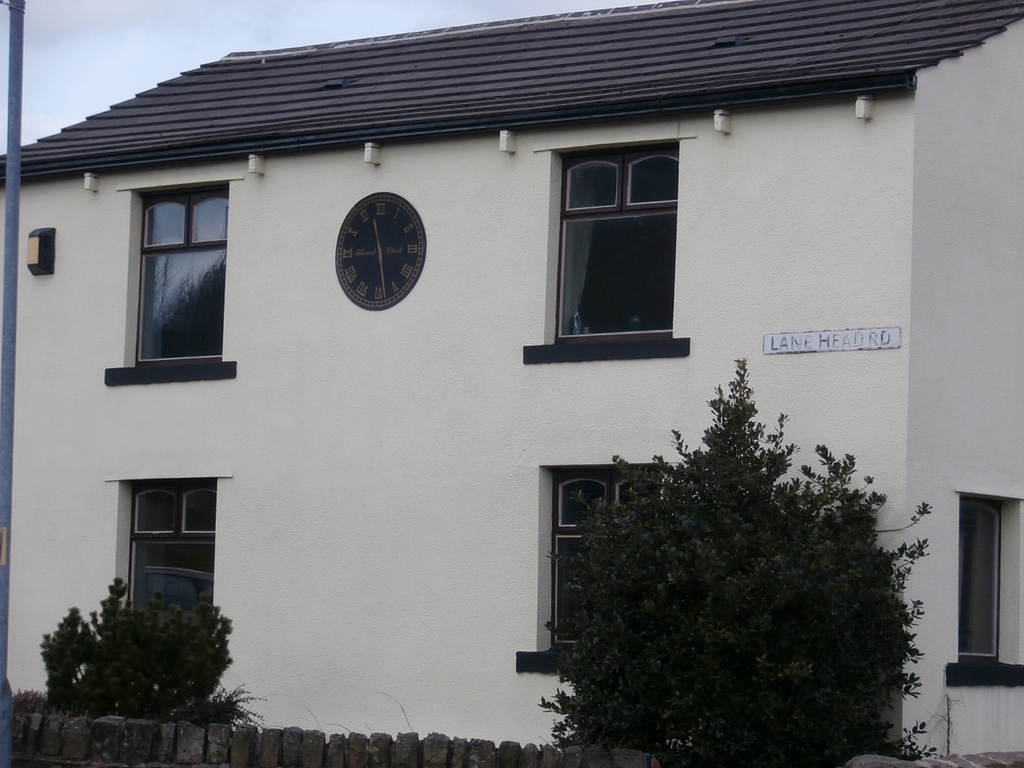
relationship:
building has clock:
[2, 1, 1024, 754] [325, 185, 440, 310]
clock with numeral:
[334, 190, 427, 311] [405, 256, 419, 283]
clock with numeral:
[334, 190, 427, 311] [400, 237, 420, 254]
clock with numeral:
[334, 190, 427, 311] [394, 218, 417, 235]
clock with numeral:
[334, 190, 427, 311] [367, 188, 393, 217]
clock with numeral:
[334, 190, 427, 311] [369, 285, 393, 304]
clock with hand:
[334, 190, 427, 311] [372, 213, 388, 248]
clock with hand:
[334, 190, 427, 311] [373, 242, 394, 306]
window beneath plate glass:
[106, 470, 215, 557] [187, 199, 230, 244]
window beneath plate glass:
[106, 470, 215, 557] [141, 199, 187, 244]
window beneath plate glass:
[106, 470, 215, 557] [177, 481, 215, 535]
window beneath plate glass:
[106, 470, 215, 557] [136, 481, 176, 535]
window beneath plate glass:
[544, 529, 586, 651] [612, 475, 651, 527]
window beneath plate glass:
[544, 529, 586, 651] [556, 475, 599, 527]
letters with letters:
[759, 325, 902, 358] [755, 336, 922, 360]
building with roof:
[2, 10, 1023, 753] [3, 4, 1022, 185]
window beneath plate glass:
[106, 470, 215, 557] [628, 153, 674, 205]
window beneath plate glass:
[106, 470, 215, 557] [565, 153, 627, 205]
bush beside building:
[553, 360, 931, 753] [2, 10, 1023, 753]